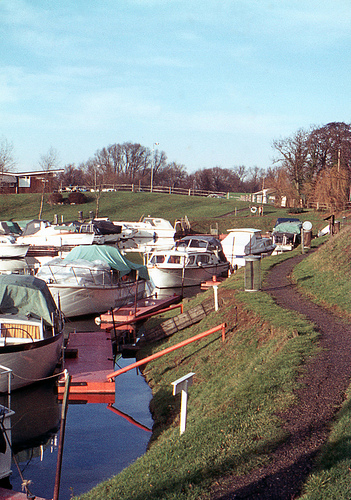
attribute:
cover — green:
[63, 247, 156, 289]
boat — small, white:
[139, 229, 231, 293]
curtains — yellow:
[2, 320, 43, 342]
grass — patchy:
[133, 191, 205, 217]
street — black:
[195, 242, 348, 497]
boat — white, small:
[89, 203, 199, 253]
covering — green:
[38, 245, 148, 283]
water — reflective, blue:
[1, 352, 151, 495]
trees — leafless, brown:
[257, 115, 349, 213]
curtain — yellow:
[5, 314, 55, 355]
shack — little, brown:
[0, 168, 64, 193]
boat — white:
[269, 228, 295, 256]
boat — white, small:
[145, 236, 227, 287]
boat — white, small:
[38, 245, 151, 319]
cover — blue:
[273, 218, 300, 236]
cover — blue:
[178, 236, 219, 250]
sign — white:
[247, 205, 256, 214]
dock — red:
[54, 289, 231, 403]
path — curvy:
[235, 263, 343, 373]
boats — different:
[0, 215, 302, 396]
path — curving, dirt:
[241, 245, 347, 495]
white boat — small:
[217, 228, 274, 268]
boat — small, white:
[219, 226, 273, 262]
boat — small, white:
[273, 218, 303, 247]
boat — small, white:
[0, 272, 63, 393]